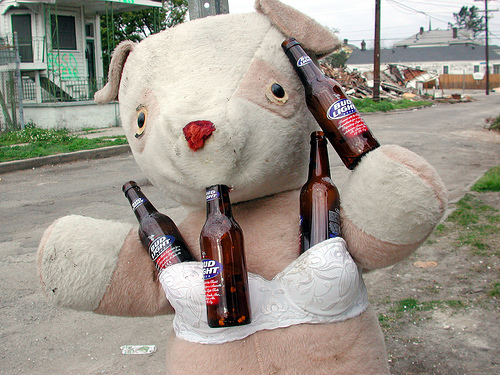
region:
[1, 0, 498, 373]
A middle class neighborhood photo.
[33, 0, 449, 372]
A white stuffed animal.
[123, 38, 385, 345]
Four bottles of Bud Light beer.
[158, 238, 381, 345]
A white strapless bra.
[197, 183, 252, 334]
A bottle of bud light in stuffed animal's mouth.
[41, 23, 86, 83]
Green colored graffiti on the house.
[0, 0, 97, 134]
The white house across the street.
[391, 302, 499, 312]
Small patches of green grass.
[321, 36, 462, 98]
A home or building of rubble.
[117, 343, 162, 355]
A smashed piece of litter on ground.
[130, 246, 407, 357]
The stuff animal has on a strapless bra.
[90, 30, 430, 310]
The stuffed animal has four beer bottle on it.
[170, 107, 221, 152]
The nose on the stuffed animal is red.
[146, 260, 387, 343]
The strapless bra is white.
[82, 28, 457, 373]
The stuffed toy is pink and white.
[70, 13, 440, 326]
The stuffed toy is large and tall.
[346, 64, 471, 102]
A pile of junk sits behind the stuffed animal.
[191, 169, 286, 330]
A beer bottle is in the stuffed animal's mouth.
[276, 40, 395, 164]
A beer bottle sits on top of the stuffed toy hand.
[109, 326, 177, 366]
A smashed can is on the street.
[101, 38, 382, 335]
four bud light bottles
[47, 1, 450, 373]
a teddy bear with beer bottles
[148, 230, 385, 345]
a white strapless bra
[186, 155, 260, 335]
bottle in the teddy bears mouth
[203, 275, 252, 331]
stuff inside the bottle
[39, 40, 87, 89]
tagging on the house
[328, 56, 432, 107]
a large wood pile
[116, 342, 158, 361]
a smashed can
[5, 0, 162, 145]
a white house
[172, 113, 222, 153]
red nose of teddy bear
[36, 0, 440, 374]
A huge stuffed bear wearing a bra, holding beer bottles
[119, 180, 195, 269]
a bottle of beer stuffed into a bra cup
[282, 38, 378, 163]
a beer bottle balanced between the bear's paw and head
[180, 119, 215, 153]
a stuffed bear's sad looking nose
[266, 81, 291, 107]
a stuffed bear's eye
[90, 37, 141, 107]
a stuffed bear's ear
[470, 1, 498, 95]
a telephone pole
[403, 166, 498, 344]
patches of grass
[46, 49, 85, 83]
graffiti written on a house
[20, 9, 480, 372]
oversized stuffed animals with beer bottles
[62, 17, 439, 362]
oversized bear with bra and beer bottles.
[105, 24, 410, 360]
empty beer bottles sitting on a stuffed teddy bear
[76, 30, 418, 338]
oversized teddy bear with red nose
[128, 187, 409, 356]
white strapless bra with a brocade pattern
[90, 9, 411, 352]
four bud light beer bottles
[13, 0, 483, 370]
green house in the background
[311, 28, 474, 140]
demolished home in the background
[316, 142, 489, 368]
sparse grass in the background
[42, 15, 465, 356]
soiled stuffed bear paws and head